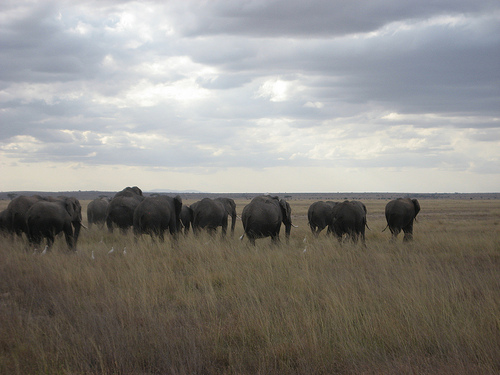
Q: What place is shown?
A: It is a field.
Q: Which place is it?
A: It is a field.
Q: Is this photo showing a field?
A: Yes, it is showing a field.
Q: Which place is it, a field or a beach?
A: It is a field.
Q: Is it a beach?
A: No, it is a field.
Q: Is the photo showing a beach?
A: No, the picture is showing a field.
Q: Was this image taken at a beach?
A: No, the picture was taken in a field.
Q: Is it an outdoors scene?
A: Yes, it is outdoors.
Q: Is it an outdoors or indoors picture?
A: It is outdoors.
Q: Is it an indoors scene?
A: No, it is outdoors.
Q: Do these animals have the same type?
A: No, there are both birds and cows.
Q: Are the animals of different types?
A: Yes, they are birds and cows.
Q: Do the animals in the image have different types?
A: Yes, they are birds and cows.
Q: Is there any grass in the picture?
A: Yes, there is grass.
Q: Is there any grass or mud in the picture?
A: Yes, there is grass.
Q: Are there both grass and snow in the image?
A: No, there is grass but no snow.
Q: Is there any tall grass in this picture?
A: Yes, there is tall grass.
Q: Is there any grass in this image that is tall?
A: Yes, there is grass that is tall.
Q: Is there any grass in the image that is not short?
A: Yes, there is tall grass.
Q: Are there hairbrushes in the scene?
A: No, there are no hairbrushes.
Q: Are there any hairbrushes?
A: No, there are no hairbrushes.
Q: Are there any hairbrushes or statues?
A: No, there are no hairbrushes or statues.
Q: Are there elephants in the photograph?
A: Yes, there are elephants.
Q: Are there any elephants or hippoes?
A: Yes, there are elephants.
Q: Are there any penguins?
A: No, there are no penguins.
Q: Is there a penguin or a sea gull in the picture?
A: No, there are no penguins or seagulls.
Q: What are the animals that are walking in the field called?
A: The animals are elephants.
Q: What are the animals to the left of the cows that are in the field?
A: The animals are elephants.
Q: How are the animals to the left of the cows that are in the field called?
A: The animals are elephants.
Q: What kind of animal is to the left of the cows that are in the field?
A: The animals are elephants.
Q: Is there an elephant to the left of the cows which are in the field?
A: Yes, there are elephants to the left of the cows.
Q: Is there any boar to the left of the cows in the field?
A: No, there are elephants to the left of the cows.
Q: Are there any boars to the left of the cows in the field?
A: No, there are elephants to the left of the cows.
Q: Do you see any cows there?
A: Yes, there are cows.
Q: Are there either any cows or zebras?
A: Yes, there are cows.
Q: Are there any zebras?
A: No, there are no zebras.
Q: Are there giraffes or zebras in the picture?
A: No, there are no zebras or giraffes.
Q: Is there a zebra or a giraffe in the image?
A: No, there are no zebras or giraffes.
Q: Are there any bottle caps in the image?
A: No, there are no bottle caps.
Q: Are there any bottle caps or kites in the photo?
A: No, there are no bottle caps or kites.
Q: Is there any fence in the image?
A: No, there are no fences.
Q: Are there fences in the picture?
A: No, there are no fences.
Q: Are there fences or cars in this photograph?
A: No, there are no fences or cars.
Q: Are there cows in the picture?
A: Yes, there are cows.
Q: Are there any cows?
A: Yes, there are cows.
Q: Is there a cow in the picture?
A: Yes, there are cows.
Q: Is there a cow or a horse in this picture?
A: Yes, there are cows.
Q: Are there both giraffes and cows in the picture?
A: No, there are cows but no giraffes.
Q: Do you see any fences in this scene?
A: No, there are no fences.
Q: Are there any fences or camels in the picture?
A: No, there are no fences or camels.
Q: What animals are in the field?
A: The animals are cows.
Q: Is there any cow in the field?
A: Yes, there are cows in the field.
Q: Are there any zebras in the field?
A: No, there are cows in the field.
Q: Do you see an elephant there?
A: Yes, there are elephants.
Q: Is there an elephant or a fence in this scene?
A: Yes, there are elephants.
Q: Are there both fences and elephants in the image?
A: No, there are elephants but no fences.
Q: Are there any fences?
A: No, there are no fences.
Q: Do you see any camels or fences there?
A: No, there are no fences or camels.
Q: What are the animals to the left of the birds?
A: The animals are elephants.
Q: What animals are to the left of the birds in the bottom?
A: The animals are elephants.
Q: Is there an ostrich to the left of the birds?
A: No, there are elephants to the left of the birds.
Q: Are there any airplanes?
A: No, there are no airplanes.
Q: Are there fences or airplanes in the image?
A: No, there are no airplanes or fences.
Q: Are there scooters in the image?
A: No, there are no scooters.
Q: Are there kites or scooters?
A: No, there are no scooters or kites.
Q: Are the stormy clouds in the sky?
A: Yes, the clouds are in the sky.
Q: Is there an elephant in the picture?
A: Yes, there are elephants.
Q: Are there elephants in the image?
A: Yes, there are elephants.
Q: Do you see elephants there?
A: Yes, there are elephants.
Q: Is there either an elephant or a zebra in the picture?
A: Yes, there are elephants.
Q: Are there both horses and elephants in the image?
A: No, there are elephants but no horses.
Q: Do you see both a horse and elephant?
A: No, there are elephants but no horses.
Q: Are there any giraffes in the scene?
A: No, there are no giraffes.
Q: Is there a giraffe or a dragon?
A: No, there are no giraffes or dragons.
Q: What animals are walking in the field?
A: The animals are elephants.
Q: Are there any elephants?
A: Yes, there are elephants.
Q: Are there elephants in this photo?
A: Yes, there are elephants.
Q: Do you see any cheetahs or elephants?
A: Yes, there are elephants.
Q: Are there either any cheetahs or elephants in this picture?
A: Yes, there are elephants.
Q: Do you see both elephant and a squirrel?
A: No, there are elephants but no squirrels.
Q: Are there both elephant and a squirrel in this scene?
A: No, there are elephants but no squirrels.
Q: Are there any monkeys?
A: No, there are no monkeys.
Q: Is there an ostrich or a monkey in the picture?
A: No, there are no monkeys or ostriches.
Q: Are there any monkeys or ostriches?
A: No, there are no monkeys or ostriches.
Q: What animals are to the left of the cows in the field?
A: The animals are elephants.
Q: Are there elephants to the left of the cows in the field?
A: Yes, there are elephants to the left of the cows.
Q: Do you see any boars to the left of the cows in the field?
A: No, there are elephants to the left of the cows.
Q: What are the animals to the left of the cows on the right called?
A: The animals are elephants.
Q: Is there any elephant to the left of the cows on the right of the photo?
A: Yes, there are elephants to the left of the cows.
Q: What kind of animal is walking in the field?
A: The animals are elephants.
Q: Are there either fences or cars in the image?
A: No, there are no fences or cars.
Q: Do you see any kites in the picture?
A: No, there are no kites.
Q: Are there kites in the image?
A: No, there are no kites.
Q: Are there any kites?
A: No, there are no kites.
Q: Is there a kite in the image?
A: No, there are no kites.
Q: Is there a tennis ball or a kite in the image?
A: No, there are no kites or tennis balls.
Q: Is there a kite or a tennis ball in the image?
A: No, there are no kites or tennis balls.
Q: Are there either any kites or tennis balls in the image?
A: No, there are no kites or tennis balls.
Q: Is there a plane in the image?
A: No, there are no airplanes.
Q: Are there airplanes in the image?
A: No, there are no airplanes.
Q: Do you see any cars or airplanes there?
A: No, there are no airplanes or cars.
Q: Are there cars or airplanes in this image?
A: No, there are no airplanes or cars.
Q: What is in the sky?
A: The clouds are in the sky.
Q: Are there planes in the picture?
A: No, there are no planes.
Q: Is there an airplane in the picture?
A: No, there are no airplanes.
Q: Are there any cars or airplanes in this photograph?
A: No, there are no airplanes or cars.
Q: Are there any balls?
A: No, there are no balls.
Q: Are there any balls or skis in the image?
A: No, there are no balls or skis.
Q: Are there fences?
A: No, there are no fences.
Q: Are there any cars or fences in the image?
A: No, there are no fences or cars.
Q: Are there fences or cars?
A: No, there are no fences or cars.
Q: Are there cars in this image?
A: No, there are no cars.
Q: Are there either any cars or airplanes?
A: No, there are no cars or airplanes.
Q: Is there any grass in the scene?
A: Yes, there is grass.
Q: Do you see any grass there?
A: Yes, there is grass.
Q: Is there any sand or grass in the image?
A: Yes, there is grass.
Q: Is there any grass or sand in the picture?
A: Yes, there is grass.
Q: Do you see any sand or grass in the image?
A: Yes, there is grass.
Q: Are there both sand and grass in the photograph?
A: No, there is grass but no sand.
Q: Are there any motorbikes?
A: No, there are no motorbikes.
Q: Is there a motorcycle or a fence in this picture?
A: No, there are no motorcycles or fences.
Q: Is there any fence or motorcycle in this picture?
A: No, there are no motorcycles or fences.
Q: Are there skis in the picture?
A: No, there are no skis.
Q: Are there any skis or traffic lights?
A: No, there are no skis or traffic lights.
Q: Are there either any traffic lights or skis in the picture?
A: No, there are no skis or traffic lights.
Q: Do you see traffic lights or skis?
A: No, there are no skis or traffic lights.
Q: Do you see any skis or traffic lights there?
A: No, there are no skis or traffic lights.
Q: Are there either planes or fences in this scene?
A: No, there are no fences or planes.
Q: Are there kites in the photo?
A: No, there are no kites.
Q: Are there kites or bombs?
A: No, there are no kites or bombs.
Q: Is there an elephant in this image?
A: Yes, there are elephants.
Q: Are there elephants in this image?
A: Yes, there are elephants.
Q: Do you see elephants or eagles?
A: Yes, there are elephants.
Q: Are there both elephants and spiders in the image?
A: No, there are elephants but no spiders.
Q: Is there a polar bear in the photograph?
A: No, there are no polar bears.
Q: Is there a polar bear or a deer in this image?
A: No, there are no polar bears or deer.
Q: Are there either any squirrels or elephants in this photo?
A: Yes, there are elephants.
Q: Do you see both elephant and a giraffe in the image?
A: No, there are elephants but no giraffes.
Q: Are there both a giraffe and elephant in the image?
A: No, there are elephants but no giraffes.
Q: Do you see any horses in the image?
A: No, there are no horses.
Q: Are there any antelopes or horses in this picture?
A: No, there are no horses or antelopes.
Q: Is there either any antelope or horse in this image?
A: No, there are no horses or antelopes.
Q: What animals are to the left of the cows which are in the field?
A: The animals are elephants.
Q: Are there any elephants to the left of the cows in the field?
A: Yes, there are elephants to the left of the cows.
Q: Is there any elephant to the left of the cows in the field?
A: Yes, there are elephants to the left of the cows.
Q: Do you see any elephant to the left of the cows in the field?
A: Yes, there are elephants to the left of the cows.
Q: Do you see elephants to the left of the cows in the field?
A: Yes, there are elephants to the left of the cows.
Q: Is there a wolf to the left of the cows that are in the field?
A: No, there are elephants to the left of the cows.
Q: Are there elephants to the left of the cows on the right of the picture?
A: Yes, there are elephants to the left of the cows.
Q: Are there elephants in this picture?
A: Yes, there are elephants.